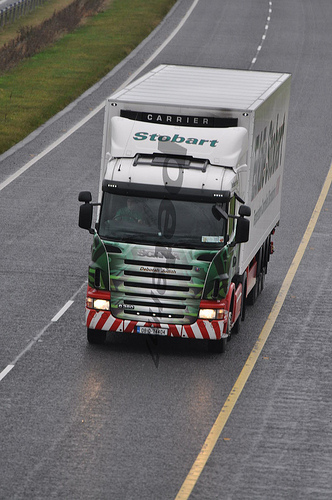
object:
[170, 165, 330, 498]
line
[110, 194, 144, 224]
man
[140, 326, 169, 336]
license plate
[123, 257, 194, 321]
vent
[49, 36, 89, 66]
grass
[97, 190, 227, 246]
windshield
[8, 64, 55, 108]
grass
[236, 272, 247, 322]
wheel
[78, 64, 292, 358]
truck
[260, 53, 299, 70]
ground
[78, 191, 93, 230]
mirror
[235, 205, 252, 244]
mirror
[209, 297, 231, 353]
wheel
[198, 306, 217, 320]
headlight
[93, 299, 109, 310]
headlight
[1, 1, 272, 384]
lines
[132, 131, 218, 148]
print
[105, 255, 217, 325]
grill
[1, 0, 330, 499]
road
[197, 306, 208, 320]
part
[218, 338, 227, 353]
edge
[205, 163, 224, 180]
part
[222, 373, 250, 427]
edge